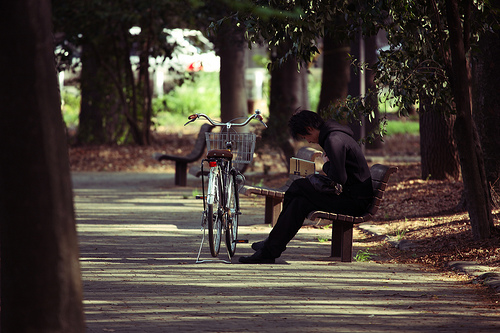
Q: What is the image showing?
A: It is showing a park.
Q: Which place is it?
A: It is a park.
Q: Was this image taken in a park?
A: Yes, it was taken in a park.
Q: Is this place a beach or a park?
A: It is a park.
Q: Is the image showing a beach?
A: No, the picture is showing a park.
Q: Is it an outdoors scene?
A: Yes, it is outdoors.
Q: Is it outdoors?
A: Yes, it is outdoors.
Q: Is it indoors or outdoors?
A: It is outdoors.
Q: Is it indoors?
A: No, it is outdoors.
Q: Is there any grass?
A: Yes, there is grass.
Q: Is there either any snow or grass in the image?
A: Yes, there is grass.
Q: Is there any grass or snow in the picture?
A: Yes, there is grass.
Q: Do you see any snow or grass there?
A: Yes, there is grass.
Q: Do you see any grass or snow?
A: Yes, there is grass.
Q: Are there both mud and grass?
A: No, there is grass but no mud.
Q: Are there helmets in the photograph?
A: No, there are no helmets.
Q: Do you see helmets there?
A: No, there are no helmets.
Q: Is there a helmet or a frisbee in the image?
A: No, there are no helmets or frisbees.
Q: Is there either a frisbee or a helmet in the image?
A: No, there are no helmets or frisbees.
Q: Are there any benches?
A: Yes, there is a bench.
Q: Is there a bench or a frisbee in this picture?
A: Yes, there is a bench.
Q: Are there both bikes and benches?
A: Yes, there are both a bench and a bike.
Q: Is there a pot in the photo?
A: No, there are no pots.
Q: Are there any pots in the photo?
A: No, there are no pots.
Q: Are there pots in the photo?
A: No, there are no pots.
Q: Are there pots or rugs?
A: No, there are no pots or rugs.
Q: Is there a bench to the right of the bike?
A: Yes, there is a bench to the right of the bike.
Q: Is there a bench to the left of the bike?
A: No, the bench is to the right of the bike.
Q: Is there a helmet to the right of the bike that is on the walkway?
A: No, there is a bench to the right of the bike.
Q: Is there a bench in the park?
A: Yes, there is a bench in the park.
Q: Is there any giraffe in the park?
A: No, there is a bench in the park.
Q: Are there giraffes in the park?
A: No, there is a bench in the park.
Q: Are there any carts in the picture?
A: No, there are no carts.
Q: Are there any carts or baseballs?
A: No, there are no carts or baseballs.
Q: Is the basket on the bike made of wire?
A: Yes, the basket is made of wire.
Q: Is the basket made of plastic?
A: No, the basket is made of wire.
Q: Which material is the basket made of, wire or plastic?
A: The basket is made of wire.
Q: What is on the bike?
A: The basket is on the bike.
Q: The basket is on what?
A: The basket is on the bike.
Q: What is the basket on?
A: The basket is on the bike.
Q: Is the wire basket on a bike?
A: Yes, the basket is on a bike.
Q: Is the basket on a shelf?
A: No, the basket is on a bike.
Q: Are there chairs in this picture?
A: Yes, there is a chair.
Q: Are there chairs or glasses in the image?
A: Yes, there is a chair.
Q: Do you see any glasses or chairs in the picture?
A: Yes, there is a chair.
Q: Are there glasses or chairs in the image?
A: Yes, there is a chair.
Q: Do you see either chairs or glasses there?
A: Yes, there is a chair.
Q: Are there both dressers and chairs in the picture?
A: No, there is a chair but no dressers.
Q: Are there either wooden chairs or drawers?
A: Yes, there is a wood chair.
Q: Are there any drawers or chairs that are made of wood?
A: Yes, the chair is made of wood.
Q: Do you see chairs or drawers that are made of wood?
A: Yes, the chair is made of wood.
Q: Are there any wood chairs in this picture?
A: Yes, there is a wood chair.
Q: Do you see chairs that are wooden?
A: Yes, there is a chair that is wooden.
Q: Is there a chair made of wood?
A: Yes, there is a chair that is made of wood.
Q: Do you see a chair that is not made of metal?
A: Yes, there is a chair that is made of wood.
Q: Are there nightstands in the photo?
A: No, there are no nightstands.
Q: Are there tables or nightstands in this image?
A: No, there are no nightstands or tables.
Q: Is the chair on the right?
A: Yes, the chair is on the right of the image.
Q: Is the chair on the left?
A: No, the chair is on the right of the image.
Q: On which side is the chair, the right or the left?
A: The chair is on the right of the image.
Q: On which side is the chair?
A: The chair is on the right of the image.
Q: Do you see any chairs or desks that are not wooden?
A: No, there is a chair but it is wooden.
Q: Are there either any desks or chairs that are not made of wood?
A: No, there is a chair but it is made of wood.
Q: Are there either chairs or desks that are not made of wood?
A: No, there is a chair but it is made of wood.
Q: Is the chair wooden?
A: Yes, the chair is wooden.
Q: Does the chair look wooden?
A: Yes, the chair is wooden.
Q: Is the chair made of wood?
A: Yes, the chair is made of wood.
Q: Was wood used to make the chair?
A: Yes, the chair is made of wood.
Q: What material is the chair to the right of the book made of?
A: The chair is made of wood.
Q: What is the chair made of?
A: The chair is made of wood.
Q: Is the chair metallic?
A: No, the chair is wooden.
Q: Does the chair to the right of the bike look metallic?
A: No, the chair is wooden.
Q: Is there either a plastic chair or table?
A: No, there is a chair but it is wooden.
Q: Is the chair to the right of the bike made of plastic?
A: No, the chair is made of wood.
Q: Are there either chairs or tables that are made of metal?
A: No, there is a chair but it is made of wood.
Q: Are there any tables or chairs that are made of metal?
A: No, there is a chair but it is made of wood.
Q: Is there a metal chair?
A: No, there is a chair but it is made of wood.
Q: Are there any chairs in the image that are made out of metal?
A: No, there is a chair but it is made of wood.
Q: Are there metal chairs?
A: No, there is a chair but it is made of wood.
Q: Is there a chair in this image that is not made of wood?
A: No, there is a chair but it is made of wood.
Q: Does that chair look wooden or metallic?
A: The chair is wooden.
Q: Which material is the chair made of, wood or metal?
A: The chair is made of wood.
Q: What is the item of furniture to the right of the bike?
A: The piece of furniture is a chair.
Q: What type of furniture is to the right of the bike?
A: The piece of furniture is a chair.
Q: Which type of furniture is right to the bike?
A: The piece of furniture is a chair.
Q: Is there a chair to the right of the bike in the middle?
A: Yes, there is a chair to the right of the bike.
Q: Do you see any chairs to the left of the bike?
A: No, the chair is to the right of the bike.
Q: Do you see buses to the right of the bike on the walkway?
A: No, there is a chair to the right of the bike.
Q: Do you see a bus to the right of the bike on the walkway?
A: No, there is a chair to the right of the bike.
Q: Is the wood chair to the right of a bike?
A: Yes, the chair is to the right of a bike.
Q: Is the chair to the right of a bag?
A: No, the chair is to the right of a bike.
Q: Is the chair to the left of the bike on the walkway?
A: No, the chair is to the right of the bike.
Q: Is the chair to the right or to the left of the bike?
A: The chair is to the right of the bike.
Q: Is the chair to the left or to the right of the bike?
A: The chair is to the right of the bike.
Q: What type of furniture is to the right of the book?
A: The piece of furniture is a chair.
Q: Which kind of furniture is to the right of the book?
A: The piece of furniture is a chair.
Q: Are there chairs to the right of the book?
A: Yes, there is a chair to the right of the book.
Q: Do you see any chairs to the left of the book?
A: No, the chair is to the right of the book.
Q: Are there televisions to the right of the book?
A: No, there is a chair to the right of the book.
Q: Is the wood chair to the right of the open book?
A: Yes, the chair is to the right of the book.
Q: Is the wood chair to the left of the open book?
A: No, the chair is to the right of the book.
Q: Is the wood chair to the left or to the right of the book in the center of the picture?
A: The chair is to the right of the book.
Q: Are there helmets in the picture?
A: No, there are no helmets.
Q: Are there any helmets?
A: No, there are no helmets.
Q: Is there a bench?
A: Yes, there is a bench.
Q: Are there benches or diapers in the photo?
A: Yes, there is a bench.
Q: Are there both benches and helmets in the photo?
A: No, there is a bench but no helmets.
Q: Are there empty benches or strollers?
A: Yes, there is an empty bench.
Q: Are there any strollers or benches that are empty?
A: Yes, the bench is empty.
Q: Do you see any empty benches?
A: Yes, there is an empty bench.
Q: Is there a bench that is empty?
A: Yes, there is a bench that is empty.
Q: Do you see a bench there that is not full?
A: Yes, there is a empty bench.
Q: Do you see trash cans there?
A: No, there are no trash cans.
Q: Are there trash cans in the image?
A: No, there are no trash cans.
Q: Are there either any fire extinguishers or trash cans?
A: No, there are no trash cans or fire extinguishers.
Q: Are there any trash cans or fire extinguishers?
A: No, there are no trash cans or fire extinguishers.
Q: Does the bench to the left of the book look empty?
A: Yes, the bench is empty.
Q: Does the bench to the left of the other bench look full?
A: No, the bench is empty.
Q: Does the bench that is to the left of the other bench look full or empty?
A: The bench is empty.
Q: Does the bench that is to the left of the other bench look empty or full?
A: The bench is empty.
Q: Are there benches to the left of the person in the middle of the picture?
A: Yes, there is a bench to the left of the person.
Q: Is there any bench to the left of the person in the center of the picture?
A: Yes, there is a bench to the left of the person.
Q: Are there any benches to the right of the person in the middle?
A: No, the bench is to the left of the person.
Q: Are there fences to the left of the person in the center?
A: No, there is a bench to the left of the person.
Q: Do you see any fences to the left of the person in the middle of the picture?
A: No, there is a bench to the left of the person.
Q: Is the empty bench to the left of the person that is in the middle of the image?
A: Yes, the bench is to the left of the person.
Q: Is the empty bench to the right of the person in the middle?
A: No, the bench is to the left of the person.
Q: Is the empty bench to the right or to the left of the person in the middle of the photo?
A: The bench is to the left of the person.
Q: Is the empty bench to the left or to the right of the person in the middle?
A: The bench is to the left of the person.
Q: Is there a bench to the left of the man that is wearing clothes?
A: Yes, there is a bench to the left of the man.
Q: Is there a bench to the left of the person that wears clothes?
A: Yes, there is a bench to the left of the man.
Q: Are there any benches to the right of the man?
A: No, the bench is to the left of the man.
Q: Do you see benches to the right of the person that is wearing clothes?
A: No, the bench is to the left of the man.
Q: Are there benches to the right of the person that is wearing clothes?
A: No, the bench is to the left of the man.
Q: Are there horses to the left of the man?
A: No, there is a bench to the left of the man.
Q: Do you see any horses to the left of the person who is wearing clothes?
A: No, there is a bench to the left of the man.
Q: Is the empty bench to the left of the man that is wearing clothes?
A: Yes, the bench is to the left of the man.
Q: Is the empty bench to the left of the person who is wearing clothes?
A: Yes, the bench is to the left of the man.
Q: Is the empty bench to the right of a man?
A: No, the bench is to the left of a man.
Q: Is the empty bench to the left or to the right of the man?
A: The bench is to the left of the man.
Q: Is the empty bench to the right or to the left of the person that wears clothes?
A: The bench is to the left of the man.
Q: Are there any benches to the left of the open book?
A: Yes, there is a bench to the left of the book.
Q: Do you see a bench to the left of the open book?
A: Yes, there is a bench to the left of the book.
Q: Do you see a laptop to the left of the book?
A: No, there is a bench to the left of the book.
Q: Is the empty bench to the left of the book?
A: Yes, the bench is to the left of the book.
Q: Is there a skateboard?
A: No, there are no skateboards.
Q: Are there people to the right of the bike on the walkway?
A: Yes, there is a person to the right of the bike.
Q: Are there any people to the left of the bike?
A: No, the person is to the right of the bike.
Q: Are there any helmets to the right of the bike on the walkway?
A: No, there is a person to the right of the bike.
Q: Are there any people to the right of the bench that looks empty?
A: Yes, there is a person to the right of the bench.